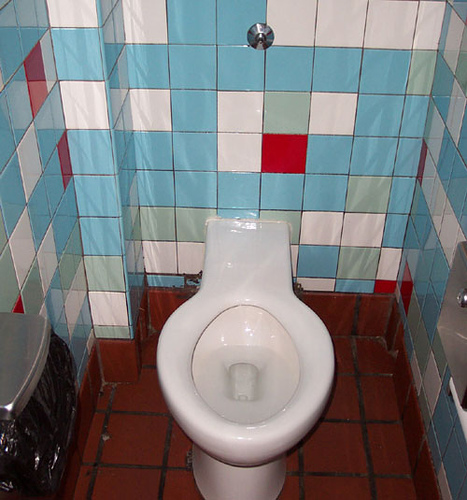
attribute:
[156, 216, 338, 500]
toilet — white, oval, clean, backless, public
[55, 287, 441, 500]
tiles — red, orange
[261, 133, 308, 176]
tile — red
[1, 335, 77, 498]
bag — plastic, black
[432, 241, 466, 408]
container — metal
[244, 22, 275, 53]
button — metal, small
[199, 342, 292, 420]
water — clear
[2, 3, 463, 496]
wall — tiled, blue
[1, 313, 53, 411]
can — silver, metal, shiny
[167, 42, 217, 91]
tile — blue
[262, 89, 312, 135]
tile — green